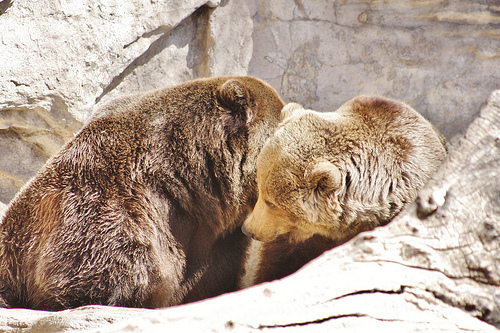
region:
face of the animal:
[216, 95, 358, 276]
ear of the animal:
[308, 146, 338, 197]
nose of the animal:
[231, 211, 269, 251]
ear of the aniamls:
[296, 150, 339, 190]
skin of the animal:
[66, 153, 129, 207]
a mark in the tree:
[254, 292, 331, 331]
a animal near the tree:
[221, 98, 498, 303]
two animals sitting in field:
[30, 81, 476, 303]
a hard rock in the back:
[128, 3, 485, 92]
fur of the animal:
[62, 135, 139, 238]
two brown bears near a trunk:
[3, 54, 461, 319]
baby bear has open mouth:
[236, 81, 451, 270]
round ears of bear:
[279, 90, 349, 197]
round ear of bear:
[210, 71, 260, 121]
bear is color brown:
[235, 87, 453, 254]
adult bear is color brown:
[2, 61, 283, 313]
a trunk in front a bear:
[231, 90, 498, 330]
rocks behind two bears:
[1, 4, 495, 305]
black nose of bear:
[234, 216, 259, 242]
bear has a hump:
[63, 78, 174, 170]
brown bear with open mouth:
[238, 186, 325, 279]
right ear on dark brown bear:
[186, 64, 259, 104]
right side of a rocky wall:
[393, 0, 460, 70]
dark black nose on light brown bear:
[236, 202, 264, 252]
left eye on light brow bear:
[259, 185, 297, 218]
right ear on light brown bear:
[266, 95, 313, 129]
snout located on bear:
[238, 217, 316, 257]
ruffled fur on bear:
[365, 101, 432, 157]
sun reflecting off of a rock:
[253, 294, 300, 321]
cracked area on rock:
[382, 235, 483, 283]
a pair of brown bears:
[55, 59, 410, 274]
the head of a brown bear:
[232, 85, 343, 266]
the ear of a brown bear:
[305, 149, 342, 194]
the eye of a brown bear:
[255, 179, 286, 216]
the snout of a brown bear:
[227, 202, 283, 243]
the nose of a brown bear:
[230, 210, 260, 240]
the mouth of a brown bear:
[277, 217, 310, 270]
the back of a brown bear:
[347, 59, 415, 139]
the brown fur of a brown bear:
[101, 176, 175, 253]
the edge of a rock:
[391, 202, 475, 279]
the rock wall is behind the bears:
[1, 2, 448, 298]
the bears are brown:
[0, 76, 445, 308]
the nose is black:
[242, 219, 259, 244]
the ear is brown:
[308, 163, 344, 195]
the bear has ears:
[238, 99, 440, 281]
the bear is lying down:
[6, 75, 275, 305]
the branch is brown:
[3, 145, 498, 331]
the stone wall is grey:
[6, 5, 498, 80]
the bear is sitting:
[236, 103, 443, 280]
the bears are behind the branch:
[11, 78, 496, 330]